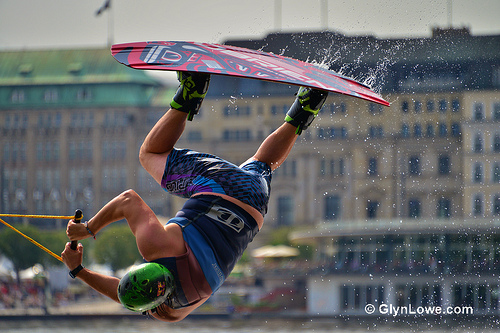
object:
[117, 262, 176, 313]
green helmet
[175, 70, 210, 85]
feet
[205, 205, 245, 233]
logo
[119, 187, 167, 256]
muscles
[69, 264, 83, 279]
watch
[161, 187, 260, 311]
tank top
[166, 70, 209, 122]
boots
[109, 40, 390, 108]
wake board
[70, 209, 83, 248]
handle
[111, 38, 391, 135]
red blue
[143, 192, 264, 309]
life vest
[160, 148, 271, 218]
shorts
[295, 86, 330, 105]
feet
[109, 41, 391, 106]
board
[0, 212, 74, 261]
rope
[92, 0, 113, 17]
flag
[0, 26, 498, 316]
building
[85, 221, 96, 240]
bracelet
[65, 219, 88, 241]
hands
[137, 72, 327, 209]
lower half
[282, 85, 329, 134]
boots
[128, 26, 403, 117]
wake board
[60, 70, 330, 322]
man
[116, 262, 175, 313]
head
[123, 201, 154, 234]
bicep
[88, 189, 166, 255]
arm